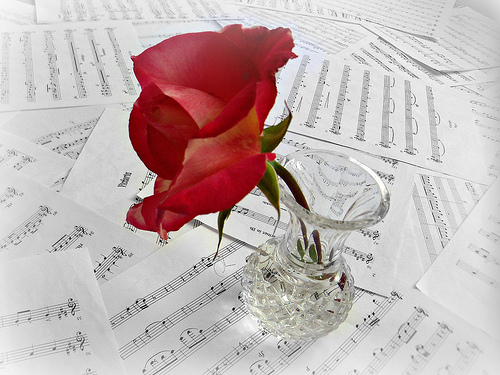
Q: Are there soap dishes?
A: No, there are no soap dishes.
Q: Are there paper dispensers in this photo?
A: No, there are no paper dispensers.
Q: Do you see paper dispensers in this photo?
A: No, there are no paper dispensers.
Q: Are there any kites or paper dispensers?
A: No, there are no paper dispensers or kites.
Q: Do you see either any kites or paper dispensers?
A: No, there are no paper dispensers or kites.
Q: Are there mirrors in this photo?
A: No, there are no mirrors.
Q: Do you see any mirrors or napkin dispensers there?
A: No, there are no mirrors or napkin dispensers.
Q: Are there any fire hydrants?
A: No, there are no fire hydrants.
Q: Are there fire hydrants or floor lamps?
A: No, there are no fire hydrants or floor lamps.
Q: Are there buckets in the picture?
A: No, there are no buckets.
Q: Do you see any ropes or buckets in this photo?
A: No, there are no buckets or ropes.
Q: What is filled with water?
A: The vase is filled with water.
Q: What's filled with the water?
A: The vase is filled with water.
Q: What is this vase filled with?
A: The vase is filled with water.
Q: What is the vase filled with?
A: The vase is filled with water.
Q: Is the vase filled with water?
A: Yes, the vase is filled with water.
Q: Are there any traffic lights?
A: No, there are no traffic lights.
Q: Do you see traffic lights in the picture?
A: No, there are no traffic lights.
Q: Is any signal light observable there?
A: No, there are no traffic lights.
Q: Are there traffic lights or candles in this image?
A: No, there are no traffic lights or candles.